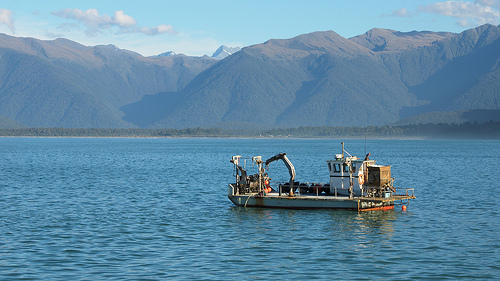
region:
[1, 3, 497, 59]
baby-blue sky with floating clouds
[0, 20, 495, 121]
slopes and angles of rocky mountains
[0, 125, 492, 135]
trees growing along base of mountain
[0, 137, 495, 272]
calm blue water under boat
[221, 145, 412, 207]
flat gray boat with curved metal arm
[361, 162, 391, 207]
elevated square brown box over platform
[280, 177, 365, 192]
railing in front of round black objects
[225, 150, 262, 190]
gray poles with panels and a connecting rod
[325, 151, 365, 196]
elevated white structure with windows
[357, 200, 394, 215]
orange stripe at rear of boat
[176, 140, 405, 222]
brown boat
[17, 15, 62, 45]
white clouds in blue sky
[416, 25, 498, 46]
white clouds in blue sky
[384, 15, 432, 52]
white clouds in blue sky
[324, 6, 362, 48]
white clouds in blue sky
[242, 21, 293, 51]
white clouds in blue sky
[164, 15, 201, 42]
white clouds in blue sky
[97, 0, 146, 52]
white clouds in blue sky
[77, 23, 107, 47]
white clouds in blue sky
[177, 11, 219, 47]
white clouds in blue sky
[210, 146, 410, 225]
boat in water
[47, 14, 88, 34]
white clouds in blue sky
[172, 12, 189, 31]
white clouds in blue sky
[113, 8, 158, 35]
white clouds in blue sky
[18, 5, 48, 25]
white clouds in blue sky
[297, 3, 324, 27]
white clouds in blue sky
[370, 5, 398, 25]
white clouds in blue sky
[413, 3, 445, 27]
white clouds in blue sky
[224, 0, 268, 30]
white clouds in blue sky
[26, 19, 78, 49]
white clouds in blue sky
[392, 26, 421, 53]
white clouds in blue sky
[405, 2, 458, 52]
white clouds in blue sky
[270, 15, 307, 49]
white clouds in blue sky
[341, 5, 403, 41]
white clouds in blue sky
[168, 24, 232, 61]
white clouds in blue sky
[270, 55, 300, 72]
white clouds in blue sky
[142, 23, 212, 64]
white clouds in blue sky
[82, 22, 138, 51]
white clouds in blue sky